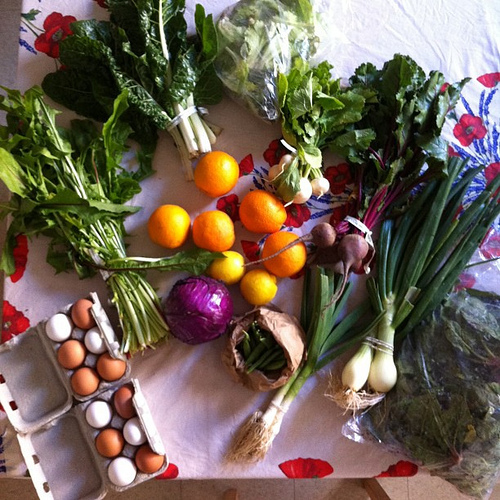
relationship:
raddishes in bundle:
[268, 64, 360, 204] [284, 133, 329, 166]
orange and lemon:
[261, 230, 306, 278] [239, 269, 278, 308]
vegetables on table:
[1, 0, 497, 500] [2, 1, 498, 499]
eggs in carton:
[1, 291, 172, 499] [2, 291, 491, 499]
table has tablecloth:
[2, 1, 498, 499] [3, 1, 489, 481]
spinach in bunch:
[2, 88, 227, 368] [75, 247, 147, 281]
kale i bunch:
[37, 2, 230, 187] [151, 100, 209, 136]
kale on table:
[37, 2, 230, 187] [2, 1, 498, 499]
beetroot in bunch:
[260, 50, 469, 288] [330, 199, 381, 258]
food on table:
[1, 0, 497, 500] [2, 1, 498, 499]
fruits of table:
[149, 150, 313, 304] [2, 1, 498, 499]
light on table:
[231, 5, 500, 228] [2, 1, 498, 499]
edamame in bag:
[228, 315, 293, 382] [224, 302, 308, 393]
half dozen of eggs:
[43, 298, 165, 492] [38, 275, 189, 496]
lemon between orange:
[207, 252, 244, 282] [260, 234, 305, 274]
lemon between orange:
[240, 269, 275, 304] [190, 208, 234, 251]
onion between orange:
[165, 277, 230, 341] [190, 208, 234, 251]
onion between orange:
[165, 277, 230, 341] [147, 203, 190, 246]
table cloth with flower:
[0, 0, 499, 480] [452, 113, 487, 145]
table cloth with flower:
[0, 0, 499, 480] [322, 162, 351, 194]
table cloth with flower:
[0, 0, 499, 480] [217, 192, 239, 219]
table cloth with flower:
[0, 0, 499, 480] [34, 12, 77, 56]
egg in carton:
[44, 313, 72, 340] [0, 290, 135, 435]